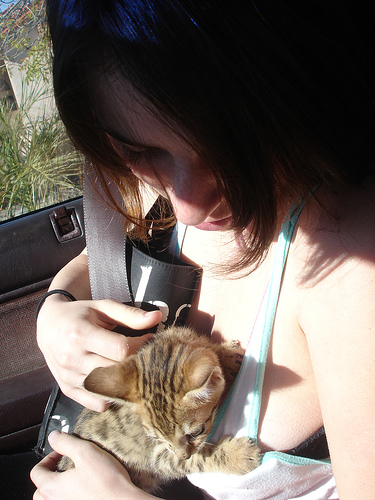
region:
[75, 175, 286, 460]
The girl is holding a kitty.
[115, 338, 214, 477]
The kitten is black and brown.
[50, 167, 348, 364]
The girl has on her seatbelt.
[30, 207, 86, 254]
The door lock on the car is down.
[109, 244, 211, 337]
The girl is carrying a black book.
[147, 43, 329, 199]
the girl has long brown hair.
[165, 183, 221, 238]
The girl nose is blemish red.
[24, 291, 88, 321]
The girl has a black rubber band on her wrist.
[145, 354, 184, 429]
The cat has black stripes on top of his head.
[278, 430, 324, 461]
The lady has on a black bra.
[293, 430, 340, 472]
black portion of the woman's bra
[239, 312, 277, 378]
white and aqua colored tank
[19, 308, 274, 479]
brown and black baby kitten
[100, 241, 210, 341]
black and white small clutch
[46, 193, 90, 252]
brown old fashion door lock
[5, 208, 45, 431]
brown leather car door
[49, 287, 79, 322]
black headband on wrist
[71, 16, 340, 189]
light brown colored hair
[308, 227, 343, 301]
shadow of the woman's hair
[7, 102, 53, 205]
green and brown plant outside car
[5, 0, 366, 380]
the woman is holding a kitten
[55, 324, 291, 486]
the kitten is gray and black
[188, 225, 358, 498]
the woman's shirt is white and blue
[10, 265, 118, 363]
a rubberband is on the woman's wrist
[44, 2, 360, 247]
the woman's hair is brown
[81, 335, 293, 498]
the kitten is looking down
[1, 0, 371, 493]
the woman is in a car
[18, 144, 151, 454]
the woman has her seat belt on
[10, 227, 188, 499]
she is holding a black object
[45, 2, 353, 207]
her hair is brown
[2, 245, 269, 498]
a cat on someones chest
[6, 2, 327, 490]
a girl holding a cat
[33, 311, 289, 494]
an orange and black cat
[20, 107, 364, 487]
a girl wearing her seatbelt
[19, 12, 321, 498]
a girl holding a kitten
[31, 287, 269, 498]
a kitten looking down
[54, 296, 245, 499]
a cat looking down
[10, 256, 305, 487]
a cat holding onto a girl's shirt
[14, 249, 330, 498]
a cat in the car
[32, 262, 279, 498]
a kitten in the car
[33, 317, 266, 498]
striped kitten in woman's arms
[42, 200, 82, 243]
lock to a car door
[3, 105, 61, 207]
green leaves outside car window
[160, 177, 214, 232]
nose of a woman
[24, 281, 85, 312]
hairband on woman's wrist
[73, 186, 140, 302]
grey seatbelt over woman's arm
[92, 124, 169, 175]
right eye of a woman looking down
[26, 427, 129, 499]
left hand of a woman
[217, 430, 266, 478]
front paw of a kitten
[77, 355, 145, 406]
right ear of a kitten